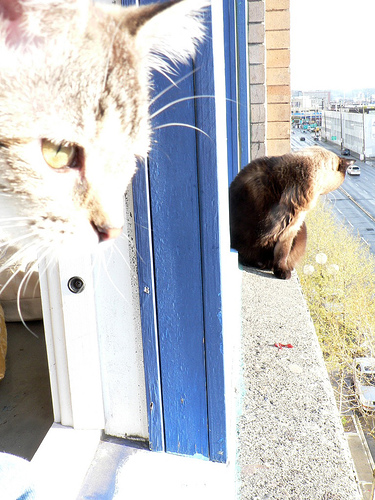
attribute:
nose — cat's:
[90, 216, 118, 244]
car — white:
[344, 162, 361, 178]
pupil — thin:
[54, 142, 64, 155]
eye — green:
[42, 135, 82, 175]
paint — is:
[115, 4, 236, 459]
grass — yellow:
[293, 195, 373, 389]